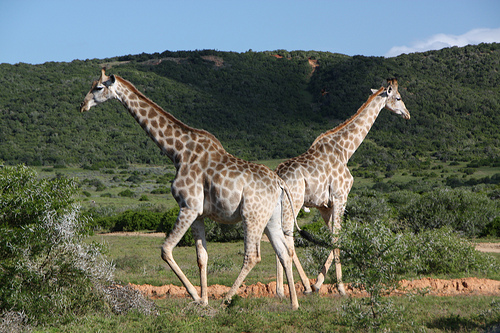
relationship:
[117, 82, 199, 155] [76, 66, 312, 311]
neck on giraffe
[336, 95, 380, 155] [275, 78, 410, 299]
neck on giraffe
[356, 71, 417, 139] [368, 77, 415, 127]
horns on head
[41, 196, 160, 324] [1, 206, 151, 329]
brush in bushes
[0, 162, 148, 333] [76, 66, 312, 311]
brush by giraffe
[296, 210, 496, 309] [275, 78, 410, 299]
bush by giraffe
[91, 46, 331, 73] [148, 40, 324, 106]
clearing on hill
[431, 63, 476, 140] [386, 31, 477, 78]
trees on hillside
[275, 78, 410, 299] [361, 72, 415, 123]
giraffe has head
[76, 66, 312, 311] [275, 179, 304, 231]
giraffe has tail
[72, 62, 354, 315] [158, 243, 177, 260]
giraffe has knee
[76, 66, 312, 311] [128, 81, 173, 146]
giraffe has neck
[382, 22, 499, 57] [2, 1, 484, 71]
clouds in distance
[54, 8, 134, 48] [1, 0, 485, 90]
blue skies in distance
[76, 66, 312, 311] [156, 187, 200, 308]
giraffe has leg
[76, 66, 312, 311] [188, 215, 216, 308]
giraffe has leg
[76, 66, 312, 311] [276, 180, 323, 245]
giraffe has tail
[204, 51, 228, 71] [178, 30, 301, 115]
dirt on mountain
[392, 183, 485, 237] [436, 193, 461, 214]
plant has leaves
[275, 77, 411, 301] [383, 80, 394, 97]
giraffe has ear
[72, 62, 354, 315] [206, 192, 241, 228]
giraffe has stomach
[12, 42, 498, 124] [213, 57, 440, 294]
hillside behind giraffes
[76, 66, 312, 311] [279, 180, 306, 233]
giraffe has tail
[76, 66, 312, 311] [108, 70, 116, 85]
giraffe has ear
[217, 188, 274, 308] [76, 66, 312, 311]
leg on giraffe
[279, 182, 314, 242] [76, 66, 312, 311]
tail on giraffe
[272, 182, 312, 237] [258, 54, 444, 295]
tail on giraffe